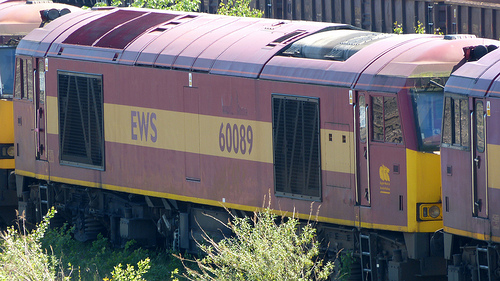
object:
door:
[269, 94, 322, 202]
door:
[54, 69, 106, 172]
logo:
[378, 164, 391, 182]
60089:
[218, 122, 256, 155]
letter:
[128, 109, 139, 140]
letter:
[137, 110, 152, 141]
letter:
[149, 113, 158, 142]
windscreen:
[416, 93, 443, 150]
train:
[11, 5, 445, 235]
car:
[11, 4, 499, 245]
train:
[8, 6, 500, 246]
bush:
[164, 187, 347, 280]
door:
[352, 88, 405, 227]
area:
[46, 94, 355, 173]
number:
[217, 119, 225, 152]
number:
[246, 123, 254, 155]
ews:
[128, 107, 160, 142]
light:
[428, 204, 441, 220]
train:
[67, 1, 499, 38]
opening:
[276, 26, 388, 63]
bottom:
[14, 169, 447, 281]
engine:
[0, 0, 50, 207]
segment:
[413, 47, 459, 281]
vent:
[265, 28, 307, 49]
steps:
[355, 232, 375, 278]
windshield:
[0, 46, 15, 98]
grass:
[2, 190, 358, 281]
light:
[6, 144, 18, 157]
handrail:
[347, 91, 377, 208]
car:
[439, 0, 499, 41]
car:
[267, 0, 437, 32]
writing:
[128, 110, 162, 146]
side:
[15, 53, 409, 227]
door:
[443, 92, 490, 219]